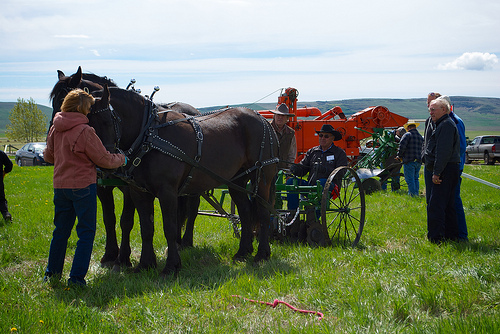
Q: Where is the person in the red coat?
A: Front of horses.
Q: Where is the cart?
A: In grass.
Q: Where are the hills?
A: Background.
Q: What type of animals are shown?
A: Horses.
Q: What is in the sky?
A: Clouds.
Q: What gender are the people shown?
A: Male.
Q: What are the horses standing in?
A: Grass.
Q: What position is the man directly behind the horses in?
A: Sitting.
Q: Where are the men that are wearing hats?
A: Behind the horses.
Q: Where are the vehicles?
A: Background.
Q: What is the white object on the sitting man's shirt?
A: Name tag.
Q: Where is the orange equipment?
A: Behind the horse and buggy.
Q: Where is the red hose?
A: Laying in the grass.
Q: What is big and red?
A: Farm device.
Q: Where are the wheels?
A: On the cart.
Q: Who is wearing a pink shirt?
A: The woman in front.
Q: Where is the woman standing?
A: In front of the horses.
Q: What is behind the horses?
A: The green cart.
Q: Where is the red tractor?
A: Behind the horses.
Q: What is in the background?
A: Rolling hills.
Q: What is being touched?
A: The horses nose.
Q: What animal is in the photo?
A: Horse.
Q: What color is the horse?
A: Brown.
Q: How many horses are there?
A: Two.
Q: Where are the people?
A: Field.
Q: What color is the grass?
A: Green.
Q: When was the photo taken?
A: Afternoon.